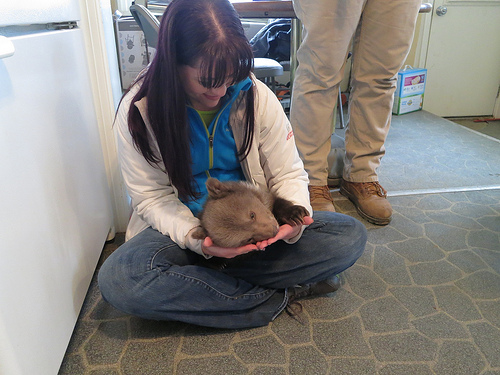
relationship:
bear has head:
[188, 175, 311, 249] [210, 196, 273, 241]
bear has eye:
[188, 175, 311, 249] [242, 210, 257, 243]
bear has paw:
[188, 175, 311, 249] [271, 204, 327, 235]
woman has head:
[92, 11, 363, 318] [131, 3, 256, 103]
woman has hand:
[92, 11, 363, 318] [188, 224, 298, 262]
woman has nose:
[92, 11, 363, 318] [208, 86, 232, 99]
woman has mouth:
[92, 11, 363, 318] [201, 90, 226, 102]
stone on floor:
[482, 171, 495, 180] [398, 112, 498, 221]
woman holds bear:
[92, 11, 363, 318] [185, 173, 325, 258]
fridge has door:
[1, 5, 90, 374] [1, 32, 91, 368]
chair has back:
[125, 5, 285, 99] [133, 4, 165, 46]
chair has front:
[125, 5, 285, 99] [251, 51, 282, 82]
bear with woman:
[188, 175, 311, 249] [92, 11, 363, 318]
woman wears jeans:
[92, 11, 363, 318] [86, 207, 385, 339]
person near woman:
[283, 0, 414, 231] [92, 11, 363, 318]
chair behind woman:
[125, 5, 285, 99] [92, 11, 363, 318]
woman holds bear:
[92, 11, 363, 318] [188, 175, 311, 249]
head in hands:
[210, 196, 273, 241] [188, 224, 298, 262]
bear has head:
[185, 173, 325, 258] [210, 196, 273, 241]